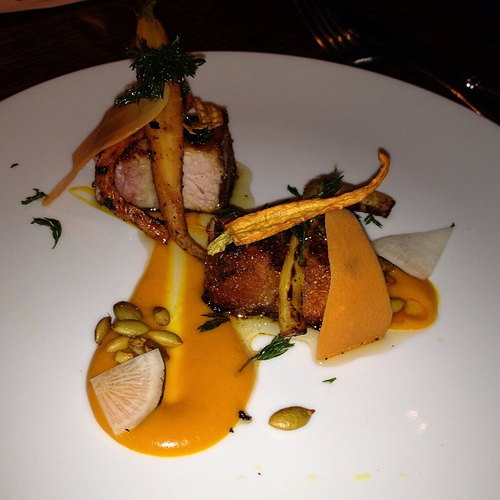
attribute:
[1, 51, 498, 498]
dish — fancy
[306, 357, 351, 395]
green — speck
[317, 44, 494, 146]
fork — silver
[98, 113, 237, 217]
meat — peice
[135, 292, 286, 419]
mustard — thick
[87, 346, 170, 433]
fruit — slice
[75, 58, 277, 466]
sauce — orange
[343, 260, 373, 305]
yellow — speck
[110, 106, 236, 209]
meat — hunk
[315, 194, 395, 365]
mango — slice